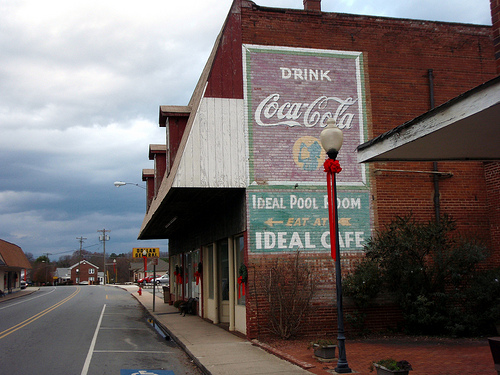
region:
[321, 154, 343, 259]
A red bow.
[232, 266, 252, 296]
A green Christmas wreath with a red bow.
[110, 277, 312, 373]
The sidewalk.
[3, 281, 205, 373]
The road.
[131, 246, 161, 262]
A black and yellow "Dollar General" sign.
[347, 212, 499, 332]
A bush against a building.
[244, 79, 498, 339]
A bricked side of a building.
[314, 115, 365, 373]
A street light.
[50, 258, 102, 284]
A red and white house.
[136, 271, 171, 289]
Parked vehicles.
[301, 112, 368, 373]
a long black street light.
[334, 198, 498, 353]
a dark green tree bush.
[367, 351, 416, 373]
a flower pot on the ground.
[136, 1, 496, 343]
a big red brick building.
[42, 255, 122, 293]
a street with houses.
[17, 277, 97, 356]
a smooth grey and yellow road.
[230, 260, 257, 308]
a green wreath.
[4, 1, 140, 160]
a cloudy white sky.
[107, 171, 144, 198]
a short white street light.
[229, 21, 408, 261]
a building advertises drink coca cola.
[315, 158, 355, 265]
Red bow attacked to a light pole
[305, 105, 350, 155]
Clear lamp cover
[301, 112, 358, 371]
Tall metal lamp post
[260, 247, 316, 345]
Small shrub with no leaves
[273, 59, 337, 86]
White lettering on brick wall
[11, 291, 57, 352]
Double yellow lines on road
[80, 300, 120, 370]
White line on the road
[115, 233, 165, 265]
Tall yellow sign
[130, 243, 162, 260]
Black letters on yellow sign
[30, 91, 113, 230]
White clouds in the sky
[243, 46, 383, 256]
sign painted on the brick wall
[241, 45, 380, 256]
coca cola advertisement painted on the wall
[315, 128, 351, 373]
light pole with a red ribbon tied to it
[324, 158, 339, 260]
red bow tied to a pole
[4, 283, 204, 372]
street in between buildings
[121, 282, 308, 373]
empty sidewalk next to a building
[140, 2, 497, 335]
red brick building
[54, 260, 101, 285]
red brick building in the background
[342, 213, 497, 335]
medium size bush next to a building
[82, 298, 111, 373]
white line painted on the street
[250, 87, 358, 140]
Coca-Cola painted in white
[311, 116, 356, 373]
old fashioned street light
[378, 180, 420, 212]
building constructed of brick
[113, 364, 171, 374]
handi-capped parking only sign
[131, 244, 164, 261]
yellow and black Dollar General sign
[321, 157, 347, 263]
red ribbon on street light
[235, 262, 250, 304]
holiday wreath with ribbon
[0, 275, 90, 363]
yellow line painted on road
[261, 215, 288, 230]
yellow arrow painted on green bricks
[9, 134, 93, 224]
white clouds in sky